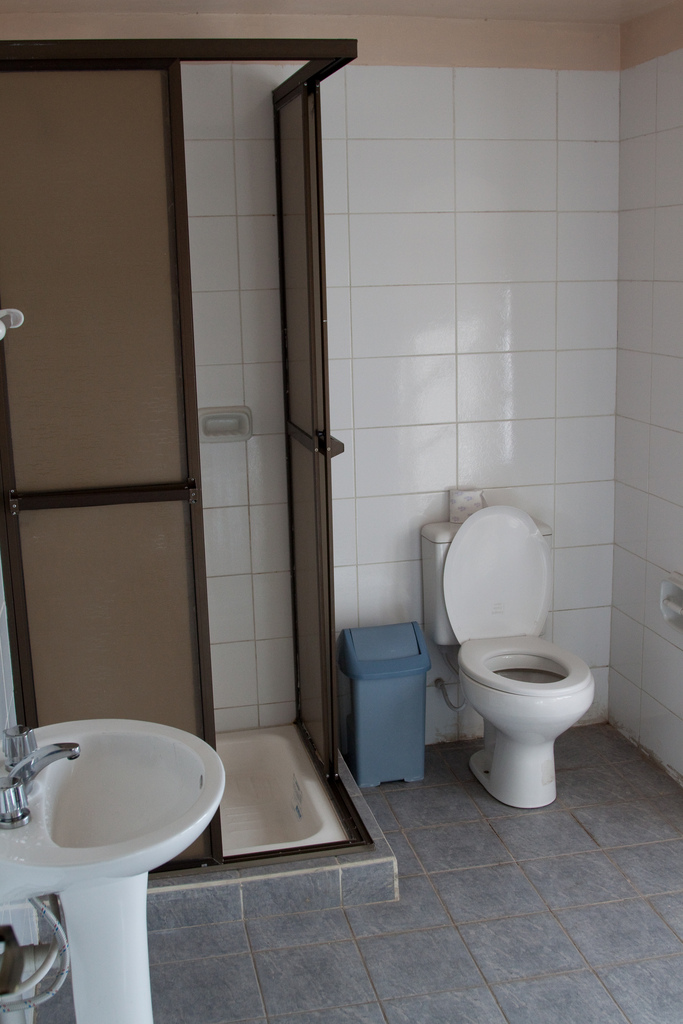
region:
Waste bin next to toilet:
[330, 610, 435, 789]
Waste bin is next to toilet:
[329, 599, 441, 789]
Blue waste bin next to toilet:
[324, 609, 437, 795]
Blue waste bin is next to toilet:
[331, 608, 449, 791]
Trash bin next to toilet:
[330, 611, 445, 791]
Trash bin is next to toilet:
[330, 608, 443, 799]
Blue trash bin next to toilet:
[332, 607, 450, 804]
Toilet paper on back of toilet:
[440, 478, 493, 532]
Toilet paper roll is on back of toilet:
[440, 479, 497, 528]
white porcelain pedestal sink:
[1, 706, 235, 1021]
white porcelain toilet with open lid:
[416, 502, 596, 813]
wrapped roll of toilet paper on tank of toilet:
[441, 486, 486, 530]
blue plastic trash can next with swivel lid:
[338, 613, 437, 796]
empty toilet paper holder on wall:
[654, 575, 681, 645]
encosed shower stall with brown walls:
[4, 37, 405, 929]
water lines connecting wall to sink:
[1, 896, 80, 1022]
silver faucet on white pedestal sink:
[2, 716, 84, 828]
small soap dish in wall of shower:
[196, 394, 255, 449]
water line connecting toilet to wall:
[428, 663, 473, 725]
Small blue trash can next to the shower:
[334, 606, 433, 784]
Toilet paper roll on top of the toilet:
[447, 483, 485, 529]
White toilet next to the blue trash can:
[415, 502, 593, 809]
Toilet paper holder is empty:
[650, 579, 681, 629]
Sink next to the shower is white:
[0, 710, 228, 1022]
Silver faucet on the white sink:
[0, 720, 87, 825]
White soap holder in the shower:
[196, 409, 253, 440]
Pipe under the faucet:
[0, 887, 67, 1021]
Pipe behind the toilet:
[428, 677, 468, 712]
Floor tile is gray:
[34, 721, 681, 1022]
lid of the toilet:
[449, 537, 534, 628]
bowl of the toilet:
[502, 666, 551, 684]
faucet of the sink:
[60, 736, 87, 768]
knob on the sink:
[0, 794, 46, 830]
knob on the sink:
[0, 725, 34, 750]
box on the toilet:
[433, 486, 492, 519]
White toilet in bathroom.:
[444, 519, 574, 799]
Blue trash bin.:
[341, 618, 429, 785]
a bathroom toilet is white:
[427, 533, 600, 808]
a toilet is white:
[381, 495, 675, 833]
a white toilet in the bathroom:
[368, 512, 630, 797]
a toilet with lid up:
[427, 495, 587, 777]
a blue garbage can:
[341, 588, 504, 789]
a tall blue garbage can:
[322, 588, 492, 780]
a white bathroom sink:
[4, 659, 297, 1020]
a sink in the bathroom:
[43, 686, 278, 1020]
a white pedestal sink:
[0, 704, 228, 1022]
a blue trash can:
[329, 617, 445, 798]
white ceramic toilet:
[419, 483, 594, 840]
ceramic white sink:
[2, 706, 260, 1016]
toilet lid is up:
[446, 505, 587, 700]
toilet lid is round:
[455, 622, 597, 703]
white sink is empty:
[0, 710, 230, 900]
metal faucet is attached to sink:
[1, 719, 81, 830]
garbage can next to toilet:
[334, 609, 438, 790]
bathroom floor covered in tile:
[36, 709, 678, 1022]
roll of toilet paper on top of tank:
[443, 481, 484, 528]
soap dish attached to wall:
[195, 400, 258, 449]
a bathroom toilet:
[411, 415, 638, 840]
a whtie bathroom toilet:
[360, 479, 679, 898]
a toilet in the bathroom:
[478, 494, 595, 753]